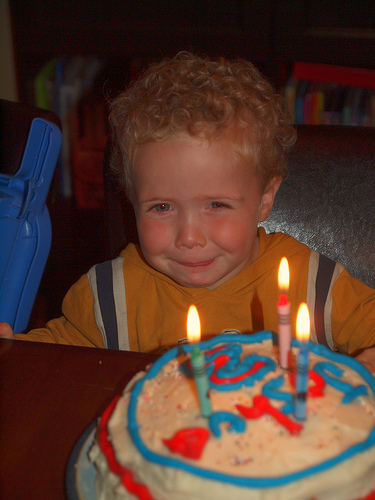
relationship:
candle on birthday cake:
[183, 302, 212, 415] [61, 330, 374, 498]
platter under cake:
[61, 415, 98, 499] [85, 253, 372, 497]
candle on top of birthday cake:
[293, 301, 311, 423] [61, 330, 374, 498]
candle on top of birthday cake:
[274, 252, 294, 369] [61, 330, 374, 498]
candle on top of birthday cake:
[183, 302, 212, 415] [61, 330, 374, 498]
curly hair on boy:
[104, 46, 295, 208] [0, 52, 371, 350]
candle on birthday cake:
[293, 301, 311, 423] [61, 330, 374, 498]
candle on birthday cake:
[274, 252, 294, 369] [61, 330, 374, 498]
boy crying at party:
[0, 52, 375, 373] [2, 4, 351, 495]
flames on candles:
[166, 254, 336, 348] [157, 289, 340, 422]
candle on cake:
[293, 301, 311, 423] [136, 364, 357, 493]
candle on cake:
[274, 252, 294, 369] [136, 364, 357, 493]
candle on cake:
[182, 340, 212, 415] [136, 364, 357, 493]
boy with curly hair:
[0, 52, 371, 350] [104, 46, 295, 208]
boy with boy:
[0, 52, 375, 373] [0, 52, 375, 373]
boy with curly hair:
[0, 52, 375, 373] [109, 50, 296, 197]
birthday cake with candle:
[61, 330, 374, 498] [296, 335, 309, 419]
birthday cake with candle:
[61, 330, 374, 498] [277, 291, 293, 367]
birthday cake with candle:
[61, 330, 374, 498] [187, 344, 213, 417]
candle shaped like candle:
[274, 252, 294, 369] [289, 300, 313, 423]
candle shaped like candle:
[274, 252, 294, 369] [183, 301, 215, 424]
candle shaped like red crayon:
[274, 252, 294, 369] [272, 292, 295, 369]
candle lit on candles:
[183, 302, 212, 415] [276, 254, 294, 374]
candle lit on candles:
[183, 302, 212, 415] [295, 302, 314, 419]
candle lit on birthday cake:
[183, 302, 212, 415] [61, 330, 374, 498]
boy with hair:
[0, 52, 375, 373] [124, 52, 261, 166]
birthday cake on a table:
[61, 330, 374, 498] [2, 335, 164, 498]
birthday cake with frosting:
[61, 330, 374, 498] [88, 324, 373, 497]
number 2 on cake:
[183, 344, 276, 389] [81, 286, 373, 485]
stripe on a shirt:
[86, 259, 128, 344] [24, 231, 329, 339]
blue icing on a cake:
[136, 453, 171, 471] [74, 325, 354, 491]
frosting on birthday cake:
[88, 324, 373, 497] [61, 330, 374, 498]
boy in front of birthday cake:
[0, 52, 371, 350] [61, 330, 374, 498]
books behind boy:
[286, 45, 371, 131] [0, 52, 371, 350]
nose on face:
[173, 205, 207, 252] [140, 187, 247, 287]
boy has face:
[0, 52, 375, 373] [140, 187, 247, 287]